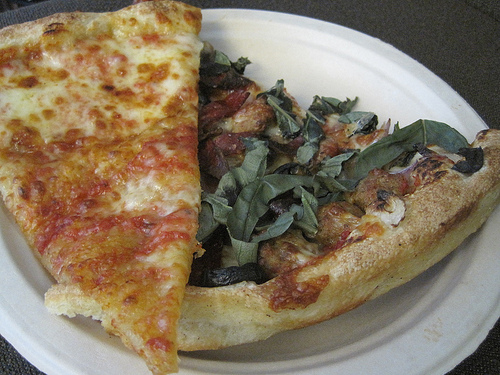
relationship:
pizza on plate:
[0, 0, 500, 371] [0, 6, 497, 373]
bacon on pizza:
[283, 112, 392, 157] [0, 0, 500, 371]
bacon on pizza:
[200, 63, 272, 163] [0, 0, 500, 371]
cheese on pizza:
[0, 0, 212, 373] [0, 2, 205, 374]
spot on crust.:
[277, 279, 311, 303] [317, 243, 417, 280]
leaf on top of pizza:
[248, 211, 296, 247] [6, 24, 326, 318]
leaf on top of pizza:
[225, 165, 326, 255] [6, 24, 326, 318]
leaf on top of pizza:
[208, 143, 276, 205] [6, 24, 326, 318]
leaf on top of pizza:
[319, 149, 360, 192] [6, 24, 326, 318]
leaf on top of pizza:
[348, 118, 480, 178] [6, 24, 326, 318]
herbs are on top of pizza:
[213, 97, 462, 231] [162, 60, 498, 334]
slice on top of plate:
[171, 32, 496, 358] [0, 6, 497, 373]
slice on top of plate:
[1, 0, 207, 374] [0, 6, 497, 373]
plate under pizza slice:
[0, 6, 497, 373] [6, 4, 208, 374]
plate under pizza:
[0, 6, 497, 373] [0, 0, 500, 371]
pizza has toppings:
[0, 0, 500, 371] [261, 99, 398, 203]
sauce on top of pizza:
[37, 169, 128, 251] [0, 2, 205, 374]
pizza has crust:
[22, 25, 196, 332] [58, 134, 495, 356]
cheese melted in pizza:
[7, 20, 192, 336] [0, 0, 500, 371]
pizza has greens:
[0, 0, 500, 371] [226, 140, 427, 250]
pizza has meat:
[0, 0, 500, 371] [199, 90, 251, 170]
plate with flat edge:
[0, 6, 497, 375] [4, 337, 49, 371]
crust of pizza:
[169, 246, 370, 334] [178, 41, 494, 350]